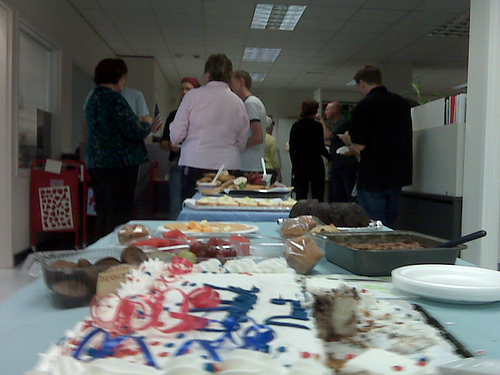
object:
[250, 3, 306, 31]
lights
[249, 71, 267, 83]
lights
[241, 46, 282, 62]
lights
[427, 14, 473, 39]
lights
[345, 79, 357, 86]
lights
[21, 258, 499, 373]
cake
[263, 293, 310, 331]
writing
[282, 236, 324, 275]
muffin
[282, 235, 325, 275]
bag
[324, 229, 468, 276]
pan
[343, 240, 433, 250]
food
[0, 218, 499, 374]
table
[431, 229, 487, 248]
utensil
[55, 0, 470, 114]
ceiling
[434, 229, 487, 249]
handle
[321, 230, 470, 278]
platter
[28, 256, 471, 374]
frosting